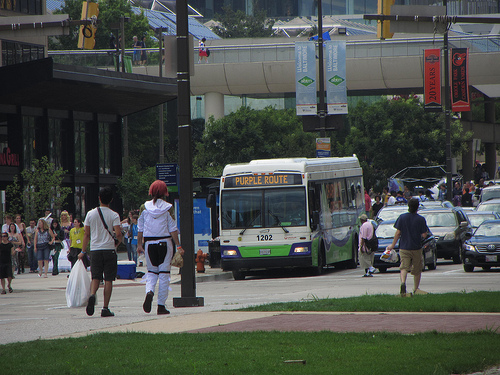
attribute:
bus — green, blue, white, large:
[218, 165, 376, 269]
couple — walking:
[88, 178, 201, 319]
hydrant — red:
[197, 244, 213, 279]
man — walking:
[387, 199, 434, 301]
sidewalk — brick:
[241, 294, 491, 338]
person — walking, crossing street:
[353, 202, 389, 275]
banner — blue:
[292, 48, 318, 112]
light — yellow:
[66, 1, 111, 49]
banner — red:
[420, 50, 446, 119]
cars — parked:
[361, 195, 496, 271]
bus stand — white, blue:
[175, 196, 223, 255]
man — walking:
[74, 196, 126, 316]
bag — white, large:
[60, 259, 101, 303]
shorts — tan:
[394, 244, 421, 276]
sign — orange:
[235, 176, 298, 189]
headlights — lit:
[212, 237, 313, 258]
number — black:
[255, 233, 271, 242]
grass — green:
[199, 341, 346, 366]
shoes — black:
[89, 294, 114, 313]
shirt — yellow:
[63, 225, 84, 249]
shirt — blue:
[393, 203, 428, 253]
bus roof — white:
[227, 158, 371, 176]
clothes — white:
[135, 199, 174, 309]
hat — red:
[151, 174, 178, 203]